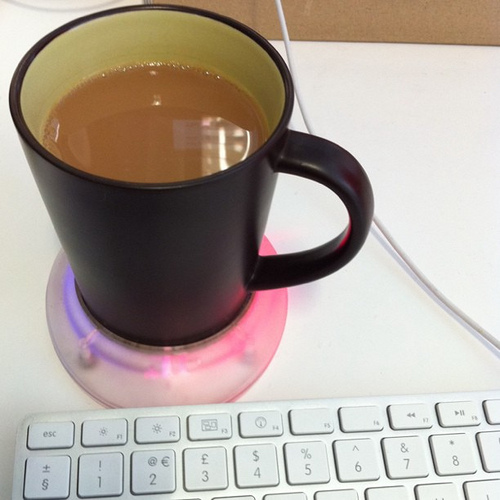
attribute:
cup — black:
[4, 3, 379, 352]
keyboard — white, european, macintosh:
[5, 386, 500, 499]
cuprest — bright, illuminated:
[43, 232, 290, 409]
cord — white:
[373, 213, 498, 357]